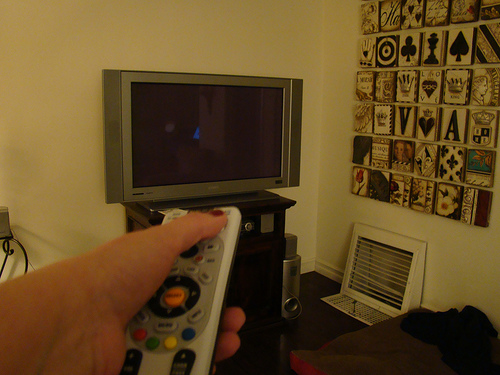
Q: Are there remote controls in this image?
A: Yes, there is a remote control.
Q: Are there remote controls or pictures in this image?
A: Yes, there is a remote control.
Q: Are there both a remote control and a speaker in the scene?
A: Yes, there are both a remote control and a speaker.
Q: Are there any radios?
A: No, there are no radios.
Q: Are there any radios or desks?
A: No, there are no radios or desks.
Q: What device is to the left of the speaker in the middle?
A: The device is a remote control.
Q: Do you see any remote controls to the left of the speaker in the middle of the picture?
A: Yes, there is a remote control to the left of the speaker.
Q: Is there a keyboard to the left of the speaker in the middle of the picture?
A: No, there is a remote control to the left of the speaker.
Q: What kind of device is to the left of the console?
A: The device is a remote control.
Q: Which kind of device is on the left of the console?
A: The device is a remote control.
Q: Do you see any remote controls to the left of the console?
A: Yes, there is a remote control to the left of the console.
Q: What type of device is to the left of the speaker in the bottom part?
A: The device is a remote control.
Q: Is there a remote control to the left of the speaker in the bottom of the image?
A: Yes, there is a remote control to the left of the speaker.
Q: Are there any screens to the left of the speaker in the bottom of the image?
A: No, there is a remote control to the left of the speaker.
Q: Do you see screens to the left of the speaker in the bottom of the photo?
A: No, there is a remote control to the left of the speaker.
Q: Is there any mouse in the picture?
A: No, there are no computer mice.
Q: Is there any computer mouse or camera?
A: No, there are no computer mice or cameras.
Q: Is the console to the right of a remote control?
A: Yes, the console is to the right of a remote control.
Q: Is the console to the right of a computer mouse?
A: No, the console is to the right of a remote control.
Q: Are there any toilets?
A: No, there are no toilets.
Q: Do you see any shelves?
A: No, there are no shelves.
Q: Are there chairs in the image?
A: No, there are no chairs.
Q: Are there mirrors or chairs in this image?
A: No, there are no chairs or mirrors.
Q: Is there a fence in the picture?
A: No, there are no fences.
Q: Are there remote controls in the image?
A: Yes, there is a remote control.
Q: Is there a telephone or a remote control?
A: Yes, there is a remote control.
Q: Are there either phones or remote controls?
A: Yes, there is a remote control.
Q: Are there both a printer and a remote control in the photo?
A: No, there is a remote control but no printers.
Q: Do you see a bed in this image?
A: No, there are no beds.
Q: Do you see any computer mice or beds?
A: No, there are no beds or computer mice.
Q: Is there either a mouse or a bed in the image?
A: No, there are no beds or computer mice.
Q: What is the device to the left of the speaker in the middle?
A: The device is a remote control.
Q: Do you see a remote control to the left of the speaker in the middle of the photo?
A: Yes, there is a remote control to the left of the speaker.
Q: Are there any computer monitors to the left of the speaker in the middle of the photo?
A: No, there is a remote control to the left of the speaker.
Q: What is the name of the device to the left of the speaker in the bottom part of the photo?
A: The device is a remote control.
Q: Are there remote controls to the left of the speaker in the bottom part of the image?
A: Yes, there is a remote control to the left of the speaker.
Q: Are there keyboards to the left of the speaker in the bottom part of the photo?
A: No, there is a remote control to the left of the speaker.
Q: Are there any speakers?
A: Yes, there is a speaker.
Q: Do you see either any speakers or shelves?
A: Yes, there is a speaker.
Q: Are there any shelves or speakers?
A: Yes, there is a speaker.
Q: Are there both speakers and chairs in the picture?
A: No, there is a speaker but no chairs.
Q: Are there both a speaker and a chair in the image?
A: No, there is a speaker but no chairs.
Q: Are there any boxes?
A: No, there are no boxes.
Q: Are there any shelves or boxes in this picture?
A: No, there are no boxes or shelves.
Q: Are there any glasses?
A: No, there are no glasses.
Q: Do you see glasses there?
A: No, there are no glasses.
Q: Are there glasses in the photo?
A: No, there are no glasses.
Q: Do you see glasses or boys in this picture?
A: No, there are no glasses or boys.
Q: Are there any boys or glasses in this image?
A: No, there are no glasses or boys.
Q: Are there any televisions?
A: Yes, there is a television.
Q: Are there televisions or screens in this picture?
A: Yes, there is a television.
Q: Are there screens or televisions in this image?
A: Yes, there is a television.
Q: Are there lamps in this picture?
A: No, there are no lamps.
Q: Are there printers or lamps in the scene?
A: No, there are no lamps or printers.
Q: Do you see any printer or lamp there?
A: No, there are no lamps or printers.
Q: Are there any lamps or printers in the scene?
A: No, there are no lamps or printers.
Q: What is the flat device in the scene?
A: The device is a television.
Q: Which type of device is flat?
A: The device is a television.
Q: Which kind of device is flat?
A: The device is a television.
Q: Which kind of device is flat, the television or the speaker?
A: The television is flat.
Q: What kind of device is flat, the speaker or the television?
A: The television is flat.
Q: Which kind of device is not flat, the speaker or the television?
A: The speaker is not flat.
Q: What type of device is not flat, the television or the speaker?
A: The speaker is not flat.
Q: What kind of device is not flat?
A: The device is a speaker.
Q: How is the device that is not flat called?
A: The device is a speaker.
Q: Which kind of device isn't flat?
A: The device is a speaker.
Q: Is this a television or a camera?
A: This is a television.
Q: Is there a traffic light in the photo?
A: No, there are no traffic lights.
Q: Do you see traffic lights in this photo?
A: No, there are no traffic lights.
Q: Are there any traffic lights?
A: No, there are no traffic lights.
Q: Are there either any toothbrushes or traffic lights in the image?
A: No, there are no traffic lights or toothbrushes.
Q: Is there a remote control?
A: Yes, there is a remote control.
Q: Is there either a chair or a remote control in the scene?
A: Yes, there is a remote control.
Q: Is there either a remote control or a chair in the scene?
A: Yes, there is a remote control.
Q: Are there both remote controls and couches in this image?
A: No, there is a remote control but no couches.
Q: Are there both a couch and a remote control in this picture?
A: No, there is a remote control but no couches.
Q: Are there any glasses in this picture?
A: No, there are no glasses.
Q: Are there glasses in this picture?
A: No, there are no glasses.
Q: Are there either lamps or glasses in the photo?
A: No, there are no glasses or lamps.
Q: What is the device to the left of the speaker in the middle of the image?
A: The device is a remote control.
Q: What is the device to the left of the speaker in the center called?
A: The device is a remote control.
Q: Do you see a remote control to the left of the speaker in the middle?
A: Yes, there is a remote control to the left of the speaker.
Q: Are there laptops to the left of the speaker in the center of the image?
A: No, there is a remote control to the left of the speaker.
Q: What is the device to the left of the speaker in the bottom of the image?
A: The device is a remote control.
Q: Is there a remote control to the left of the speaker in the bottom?
A: Yes, there is a remote control to the left of the speaker.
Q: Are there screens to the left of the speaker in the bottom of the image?
A: No, there is a remote control to the left of the speaker.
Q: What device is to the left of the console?
A: The device is a remote control.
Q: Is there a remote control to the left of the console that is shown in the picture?
A: Yes, there is a remote control to the left of the console.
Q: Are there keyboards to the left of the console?
A: No, there is a remote control to the left of the console.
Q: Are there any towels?
A: No, there are no towels.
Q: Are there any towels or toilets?
A: No, there are no towels or toilets.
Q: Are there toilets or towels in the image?
A: No, there are no towels or toilets.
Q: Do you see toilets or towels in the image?
A: No, there are no towels or toilets.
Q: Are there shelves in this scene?
A: No, there are no shelves.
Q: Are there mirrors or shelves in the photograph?
A: No, there are no shelves or mirrors.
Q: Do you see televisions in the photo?
A: Yes, there is a television.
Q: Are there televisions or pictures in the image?
A: Yes, there is a television.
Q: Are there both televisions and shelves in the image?
A: No, there is a television but no shelves.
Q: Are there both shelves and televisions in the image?
A: No, there is a television but no shelves.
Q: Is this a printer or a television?
A: This is a television.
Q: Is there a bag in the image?
A: No, there are no bags.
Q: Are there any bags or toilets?
A: No, there are no bags or toilets.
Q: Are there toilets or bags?
A: No, there are no bags or toilets.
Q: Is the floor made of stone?
A: No, the floor is made of hardwood.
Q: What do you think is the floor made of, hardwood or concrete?
A: The floor is made of hardwood.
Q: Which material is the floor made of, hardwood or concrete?
A: The floor is made of hardwood.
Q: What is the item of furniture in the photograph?
A: The piece of furniture is a TV stand.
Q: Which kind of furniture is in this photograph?
A: The furniture is a TV stand.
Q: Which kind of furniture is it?
A: The piece of furniture is a TV stand.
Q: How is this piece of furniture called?
A: That is a TV stand.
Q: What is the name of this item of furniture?
A: That is a TV stand.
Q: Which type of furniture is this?
A: That is a TV stand.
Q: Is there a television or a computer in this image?
A: Yes, there is a television.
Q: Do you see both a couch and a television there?
A: No, there is a television but no couches.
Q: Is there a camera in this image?
A: No, there are no cameras.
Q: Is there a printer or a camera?
A: No, there are no cameras or printers.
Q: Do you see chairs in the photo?
A: No, there are no chairs.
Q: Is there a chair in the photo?
A: No, there are no chairs.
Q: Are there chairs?
A: No, there are no chairs.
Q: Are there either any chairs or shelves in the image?
A: No, there are no chairs or shelves.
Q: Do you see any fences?
A: No, there are no fences.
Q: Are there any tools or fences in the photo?
A: No, there are no fences or tools.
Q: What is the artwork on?
A: The artwork is on the wall.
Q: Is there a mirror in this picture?
A: No, there are no mirrors.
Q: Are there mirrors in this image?
A: No, there are no mirrors.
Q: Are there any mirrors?
A: No, there are no mirrors.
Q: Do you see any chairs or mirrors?
A: No, there are no mirrors or chairs.